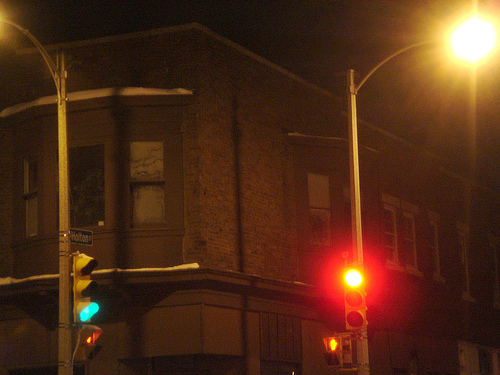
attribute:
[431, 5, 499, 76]
street light — glowing, yellow, on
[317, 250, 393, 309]
light — glowing, red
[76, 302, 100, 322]
green light — on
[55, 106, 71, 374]
pole — light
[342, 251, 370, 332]
signal — red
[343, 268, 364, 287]
right light — red, on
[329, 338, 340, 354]
light — red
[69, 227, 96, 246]
street sign — green, white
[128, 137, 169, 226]
window — boarded up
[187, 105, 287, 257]
bricks — brown